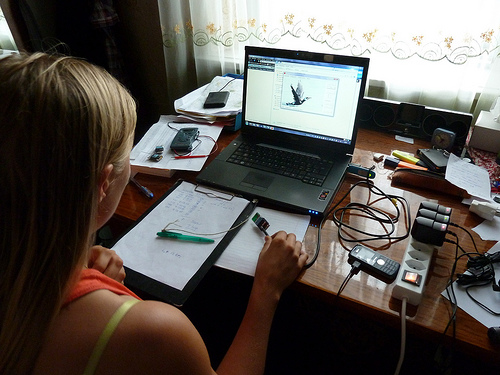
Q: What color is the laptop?
A: Black.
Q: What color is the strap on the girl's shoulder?
A: Yellow.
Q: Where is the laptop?
A: On top of the table.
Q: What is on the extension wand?
A: Chargers.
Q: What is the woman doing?
A: Looking at her work.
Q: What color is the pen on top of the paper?
A: Green.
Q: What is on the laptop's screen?
A: A bird.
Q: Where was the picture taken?
A: In a office.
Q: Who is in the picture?
A: A woman.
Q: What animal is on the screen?
A: A bird.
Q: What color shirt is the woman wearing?
A: Orange.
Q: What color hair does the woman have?
A: Blonde.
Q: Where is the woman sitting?
A: At a desk.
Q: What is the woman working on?
A: A computer.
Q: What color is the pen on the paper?
A: Green.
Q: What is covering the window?
A: A curtain.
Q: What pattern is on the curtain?
A: Flowers.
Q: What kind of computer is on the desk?
A: A laptop.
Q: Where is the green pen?
A: In front of the girl on the clipboard.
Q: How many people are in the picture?
A: One.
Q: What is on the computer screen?
A: Duck.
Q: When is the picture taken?
A: During the daytime.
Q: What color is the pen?
A: Green.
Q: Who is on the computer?
A: A girl.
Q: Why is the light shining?
A: It is sunny.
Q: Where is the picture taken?
A: At a home desk.